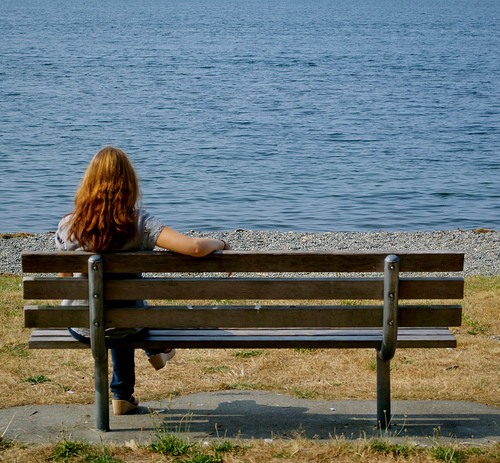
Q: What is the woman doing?
A: Sitting down.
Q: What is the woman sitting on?
A: A bench.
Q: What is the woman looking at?
A: A body of water.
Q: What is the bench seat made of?
A: Wood.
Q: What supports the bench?
A: Two metal poles.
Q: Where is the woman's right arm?
A: Resting on the bench.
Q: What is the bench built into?
A: Concrete.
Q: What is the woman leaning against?
A: The back of a wooden bench.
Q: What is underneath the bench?
A: A shadow.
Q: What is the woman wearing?
A: A gray shirt and blue jeans.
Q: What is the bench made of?
A: Wood and metal.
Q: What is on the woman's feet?
A: Shoes.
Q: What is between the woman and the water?
A: Gravel.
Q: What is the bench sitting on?
A: A concrete sidewalk.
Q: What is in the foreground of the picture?
A: Brown and green grass.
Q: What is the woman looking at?
A: The water.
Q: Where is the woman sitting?
A: On a bench.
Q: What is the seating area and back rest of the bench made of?
A: Wood.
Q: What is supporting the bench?
A: Metal poles.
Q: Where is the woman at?
A: A beach.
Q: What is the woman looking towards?
A: The water.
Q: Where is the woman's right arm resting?
A: On the back of the bench.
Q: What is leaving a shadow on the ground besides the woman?
A: The bench.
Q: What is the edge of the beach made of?
A: Rocks.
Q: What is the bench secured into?
A: Cement.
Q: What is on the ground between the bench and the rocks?
A: Grass.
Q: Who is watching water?
A: Lady.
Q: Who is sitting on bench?
A: A lady.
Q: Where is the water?
A: In front of lady.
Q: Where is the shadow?
A: On ground.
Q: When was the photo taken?
A: Daytime.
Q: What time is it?
A: Afternoon.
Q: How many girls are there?
A: One.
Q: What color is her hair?
A: Brown.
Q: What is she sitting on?
A: A bench.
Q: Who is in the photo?
A: A lady.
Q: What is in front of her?
A: Water.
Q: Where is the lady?
A: Neat the water.